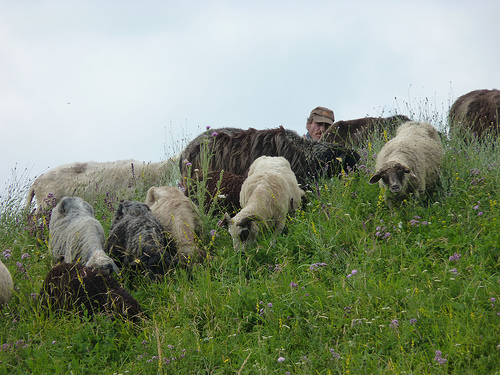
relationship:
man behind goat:
[301, 106, 336, 141] [47, 195, 117, 301]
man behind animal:
[301, 106, 336, 141] [24, 158, 174, 223]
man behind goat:
[301, 106, 336, 141] [371, 122, 446, 206]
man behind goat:
[301, 106, 336, 141] [225, 153, 302, 250]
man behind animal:
[301, 106, 336, 141] [178, 127, 362, 188]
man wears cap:
[301, 108, 340, 145] [308, 105, 337, 127]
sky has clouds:
[4, 2, 496, 189] [45, 14, 370, 120]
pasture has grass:
[7, 122, 499, 370] [189, 241, 489, 371]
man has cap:
[301, 106, 336, 141] [307, 106, 335, 125]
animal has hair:
[178, 122, 370, 207] [184, 113, 337, 185]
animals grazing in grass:
[222, 156, 305, 256] [0, 227, 494, 373]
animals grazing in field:
[222, 156, 305, 256] [8, 69, 470, 361]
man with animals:
[301, 106, 336, 141] [28, 160, 300, 321]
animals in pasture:
[28, 160, 300, 321] [5, 194, 497, 373]